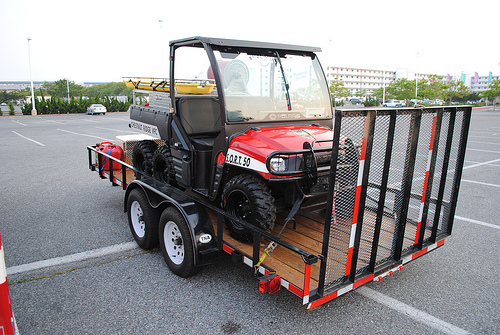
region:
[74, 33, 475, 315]
this is a tracktor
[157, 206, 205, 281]
this is a tyre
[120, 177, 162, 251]
this is a tyre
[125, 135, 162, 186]
this is a tyre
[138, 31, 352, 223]
A small utility truck on a trailer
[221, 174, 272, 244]
A front tire on a utility truck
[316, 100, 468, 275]
A metal barrier on a trailer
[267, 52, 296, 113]
A windshield wiper on a small truck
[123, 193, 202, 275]
Wheels on a trailer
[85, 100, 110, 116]
A car in a parking lot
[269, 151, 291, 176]
A headlight on a small truck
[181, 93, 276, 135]
A black bench seat in a small truck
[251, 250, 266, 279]
Yellow end of a tie down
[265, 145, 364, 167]
Metal bar on a small utility truck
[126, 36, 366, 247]
A small cart on a trailer.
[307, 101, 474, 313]
A side of a trailer.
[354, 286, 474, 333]
A white line on a parking lot.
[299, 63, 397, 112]
A tall multi story white building.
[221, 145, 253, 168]
I.D. on the side of a cart.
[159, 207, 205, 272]
A wheel on a trailer.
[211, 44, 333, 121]
A windshield on a small vehicle.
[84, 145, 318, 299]
A railing on a trailer.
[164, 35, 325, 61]
A roof on a small vehicle.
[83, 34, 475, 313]
a all terrain vehicle on a trailer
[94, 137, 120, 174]
a red gas can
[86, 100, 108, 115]
a silver car parked in a lot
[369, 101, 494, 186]
a large empty parking lot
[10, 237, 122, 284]
a white line painted on a parking lot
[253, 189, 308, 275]
a rope tied to a trailer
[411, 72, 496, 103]
several flags and flag poles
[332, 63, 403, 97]
a white building with several levels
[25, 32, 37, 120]
a tall light on a pole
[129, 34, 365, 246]
A red and black sport utility vehicle.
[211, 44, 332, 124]
A Clear wide windshield.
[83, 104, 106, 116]
A parked white car.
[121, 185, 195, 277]
Two black and white trailer wheels.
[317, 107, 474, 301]
A dark metal gate on a trailer.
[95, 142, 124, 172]
Red gas can on a trailer.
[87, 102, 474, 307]
A small brown and black trailer.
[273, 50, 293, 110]
Black windshield wiper coming down the windshield.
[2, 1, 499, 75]
A white sky.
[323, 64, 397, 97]
Longest whitest building.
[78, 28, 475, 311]
trailer holding small red vehicle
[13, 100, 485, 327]
large grey parking lot containing vehicle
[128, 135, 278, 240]
three black tires visible on vehicle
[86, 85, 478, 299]
trailer lined with orange and white hazard tape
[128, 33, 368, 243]
vehicle is on trailer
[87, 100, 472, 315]
trailer is underneath vehicle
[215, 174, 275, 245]
black tire is round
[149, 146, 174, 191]
black tire is round